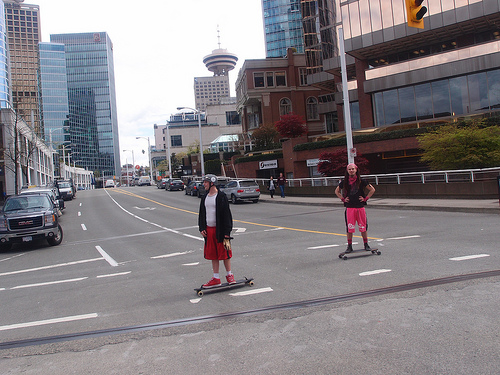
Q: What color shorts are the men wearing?
A: Red.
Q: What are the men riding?
A: Skateboards.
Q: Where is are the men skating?
A: The street.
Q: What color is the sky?
A: White.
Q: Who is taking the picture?
A: A photographer.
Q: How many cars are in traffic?
A: None.